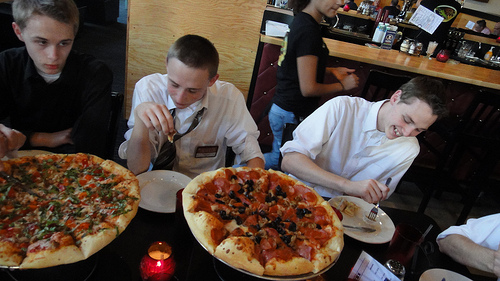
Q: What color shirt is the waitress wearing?
A: Black.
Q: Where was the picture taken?
A: At a restaurant.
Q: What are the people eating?
A: Pizza.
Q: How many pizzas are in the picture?
A: Two.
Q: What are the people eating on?
A: Plates.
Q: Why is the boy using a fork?
A: To eat with.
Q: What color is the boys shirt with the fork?
A: White.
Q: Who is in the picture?
A: Three young boys.